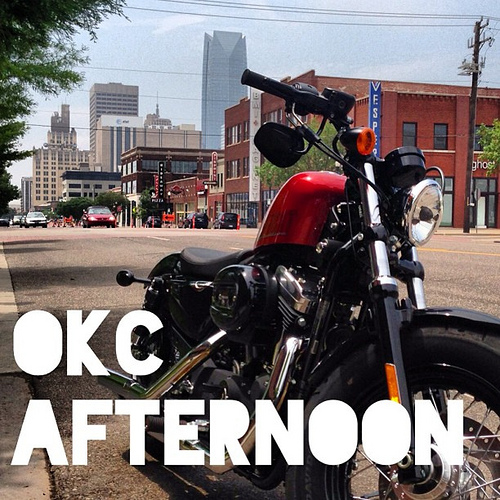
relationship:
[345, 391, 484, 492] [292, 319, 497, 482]
spokes on tire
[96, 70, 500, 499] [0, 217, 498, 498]
motorbike parked on side of road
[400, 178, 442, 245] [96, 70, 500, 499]
headlight on motorbike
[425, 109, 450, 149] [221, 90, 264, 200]
window on brick building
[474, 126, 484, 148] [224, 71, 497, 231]
window on building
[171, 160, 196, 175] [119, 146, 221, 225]
window on building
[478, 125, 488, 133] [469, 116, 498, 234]
leaf of tree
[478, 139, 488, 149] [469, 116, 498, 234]
leaf of tree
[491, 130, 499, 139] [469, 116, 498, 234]
leaf of tree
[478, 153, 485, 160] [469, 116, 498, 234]
leaf of tree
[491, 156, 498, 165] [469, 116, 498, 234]
leaf of tree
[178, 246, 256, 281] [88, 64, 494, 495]
black seat of motorbike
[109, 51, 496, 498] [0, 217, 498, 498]
bike parked on road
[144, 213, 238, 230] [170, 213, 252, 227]
parked cars on street meter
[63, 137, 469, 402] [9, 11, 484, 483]
motorbike in photo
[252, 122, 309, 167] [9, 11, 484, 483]
side mirror in photo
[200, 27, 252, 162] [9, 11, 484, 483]
building in photo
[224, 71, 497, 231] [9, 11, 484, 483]
building in photo